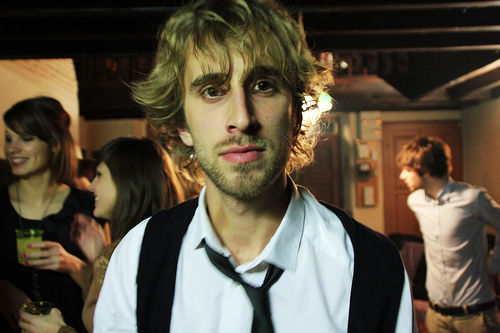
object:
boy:
[396, 136, 500, 333]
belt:
[430, 299, 498, 316]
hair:
[120, 0, 332, 188]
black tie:
[205, 243, 286, 333]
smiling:
[4, 129, 49, 174]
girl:
[0, 95, 112, 333]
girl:
[75, 137, 184, 333]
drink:
[15, 229, 42, 264]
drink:
[21, 295, 52, 316]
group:
[0, 0, 500, 333]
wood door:
[381, 121, 463, 237]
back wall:
[340, 111, 383, 235]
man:
[92, 0, 412, 332]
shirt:
[92, 172, 416, 333]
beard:
[193, 127, 292, 200]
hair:
[396, 136, 453, 180]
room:
[0, 0, 500, 333]